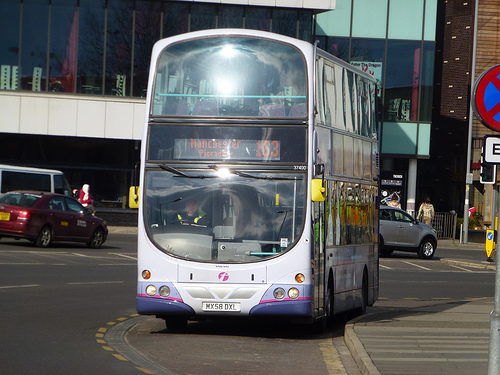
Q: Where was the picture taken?
A: At a bus stop.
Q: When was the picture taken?
A: Daytime.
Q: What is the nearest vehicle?
A: A bus.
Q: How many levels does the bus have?
A: Two.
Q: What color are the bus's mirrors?
A: Yellow.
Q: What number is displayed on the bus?
A: 163.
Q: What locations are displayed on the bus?
A: Manchester Piccadilly.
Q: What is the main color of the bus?
A: White.